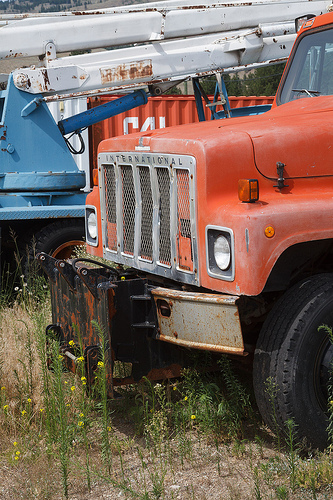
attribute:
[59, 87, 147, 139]
shock — blue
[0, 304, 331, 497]
ground — brown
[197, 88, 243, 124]
wiper — windshield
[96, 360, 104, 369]
flowers — yellow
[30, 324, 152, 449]
flowers — yellow 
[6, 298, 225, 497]
weeds — green 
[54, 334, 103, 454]
flowers — yellow 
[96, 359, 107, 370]
flower — yellow 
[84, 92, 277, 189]
trailer — orange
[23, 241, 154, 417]
machinery — heavy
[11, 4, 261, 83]
machinery — white, hydrolic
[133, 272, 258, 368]
bumper — rusty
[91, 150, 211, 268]
grate — metal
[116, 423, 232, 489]
ground — tan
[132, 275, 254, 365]
part — broken